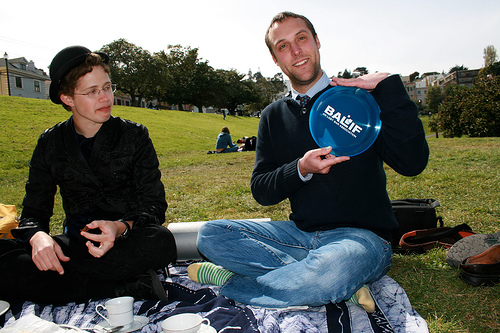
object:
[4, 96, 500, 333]
grass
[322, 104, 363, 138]
writing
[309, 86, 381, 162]
frisbee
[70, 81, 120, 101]
glasses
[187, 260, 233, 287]
sock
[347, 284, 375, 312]
sock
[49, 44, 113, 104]
hat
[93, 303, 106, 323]
handle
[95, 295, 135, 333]
mug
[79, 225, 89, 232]
object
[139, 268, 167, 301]
shoes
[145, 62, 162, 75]
leaves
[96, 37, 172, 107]
trees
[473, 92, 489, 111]
leaves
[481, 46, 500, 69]
trees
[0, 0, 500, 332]
picnic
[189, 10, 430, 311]
person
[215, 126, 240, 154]
woman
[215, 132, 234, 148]
hoodie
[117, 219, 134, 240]
watch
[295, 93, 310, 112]
tie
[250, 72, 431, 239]
sweater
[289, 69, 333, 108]
dress shirt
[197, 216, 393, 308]
jeans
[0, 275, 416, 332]
blanket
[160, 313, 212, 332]
tea cup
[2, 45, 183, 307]
people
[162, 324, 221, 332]
saucer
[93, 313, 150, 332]
saucer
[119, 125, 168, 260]
arm